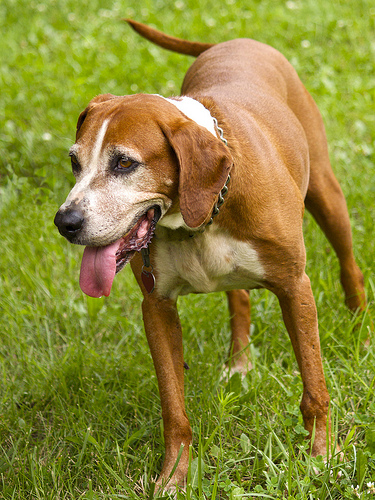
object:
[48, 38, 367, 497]
dog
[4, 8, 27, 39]
grass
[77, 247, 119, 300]
tongue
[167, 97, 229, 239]
collar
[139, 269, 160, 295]
heart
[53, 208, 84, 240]
nose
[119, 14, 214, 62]
tail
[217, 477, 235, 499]
clover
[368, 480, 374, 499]
flowers